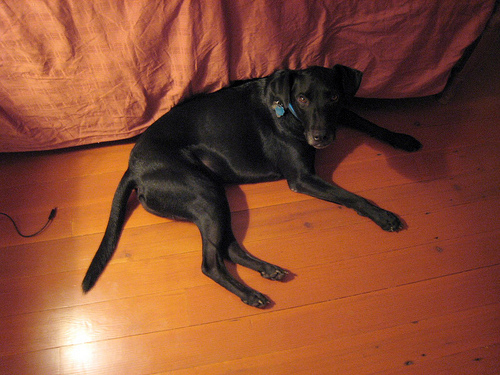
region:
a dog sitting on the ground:
[61, 57, 428, 309]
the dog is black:
[66, 52, 433, 312]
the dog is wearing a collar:
[261, 76, 312, 132]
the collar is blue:
[263, 78, 305, 134]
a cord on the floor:
[2, 198, 62, 247]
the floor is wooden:
[2, 92, 499, 369]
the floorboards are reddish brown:
[2, 87, 491, 372]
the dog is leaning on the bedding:
[3, 2, 498, 157]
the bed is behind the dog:
[0, 9, 498, 164]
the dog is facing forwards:
[70, 61, 429, 311]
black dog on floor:
[69, 38, 432, 320]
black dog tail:
[76, 162, 148, 309]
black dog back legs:
[142, 180, 302, 331]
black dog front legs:
[347, 108, 434, 243]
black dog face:
[273, 59, 361, 155]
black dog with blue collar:
[75, 59, 450, 327]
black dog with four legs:
[73, 41, 436, 332]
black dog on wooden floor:
[63, 47, 450, 326]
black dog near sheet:
[56, 8, 459, 343]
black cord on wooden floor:
[2, 194, 71, 262]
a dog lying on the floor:
[70, 52, 441, 312]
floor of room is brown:
[12, 77, 499, 370]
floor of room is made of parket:
[3, 137, 498, 369]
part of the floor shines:
[33, 280, 131, 373]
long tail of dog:
[71, 165, 140, 294]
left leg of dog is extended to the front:
[347, 111, 442, 163]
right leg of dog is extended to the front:
[298, 171, 408, 238]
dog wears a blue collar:
[282, 51, 353, 156]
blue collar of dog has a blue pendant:
[267, 91, 307, 128]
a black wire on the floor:
[1, 193, 63, 245]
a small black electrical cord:
[0, 204, 58, 239]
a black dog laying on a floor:
[80, 65, 426, 308]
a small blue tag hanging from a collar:
[272, 103, 284, 118]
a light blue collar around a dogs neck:
[284, 98, 302, 122]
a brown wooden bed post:
[433, 3, 498, 108]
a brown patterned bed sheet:
[0, 2, 499, 153]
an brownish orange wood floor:
[0, 22, 498, 372]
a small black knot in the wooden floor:
[404, 358, 415, 367]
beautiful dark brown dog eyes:
[294, 91, 341, 108]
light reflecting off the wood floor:
[27, 277, 153, 373]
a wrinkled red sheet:
[1, 0, 498, 150]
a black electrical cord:
[0, 206, 58, 238]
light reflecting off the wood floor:
[50, 308, 125, 371]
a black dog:
[80, 61, 424, 310]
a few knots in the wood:
[378, 318, 428, 367]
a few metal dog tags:
[273, 103, 286, 120]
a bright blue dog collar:
[282, 102, 306, 122]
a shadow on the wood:
[223, 180, 265, 250]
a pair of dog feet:
[238, 260, 287, 308]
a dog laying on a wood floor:
[72, 63, 427, 315]